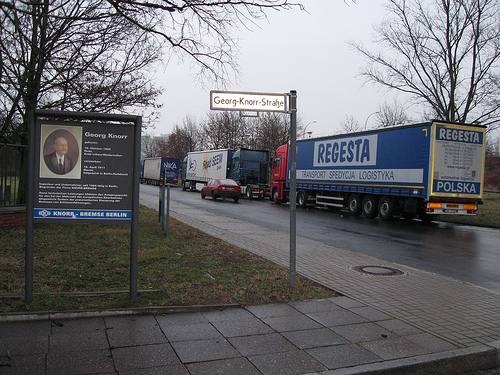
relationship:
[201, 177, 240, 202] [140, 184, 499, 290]
car on street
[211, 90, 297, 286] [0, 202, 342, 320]
sign on grass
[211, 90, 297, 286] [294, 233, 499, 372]
sign on corner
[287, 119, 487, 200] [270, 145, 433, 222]
trailer on semi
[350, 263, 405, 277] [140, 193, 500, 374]
man hole on sidewalk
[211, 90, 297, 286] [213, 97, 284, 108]
sign has lettering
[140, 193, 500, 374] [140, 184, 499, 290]
sidewalk next to street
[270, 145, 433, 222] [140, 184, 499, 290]
semi on street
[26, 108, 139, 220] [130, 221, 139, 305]
sign on pole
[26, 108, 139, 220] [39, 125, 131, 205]
sign has words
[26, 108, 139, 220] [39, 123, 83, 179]
sign has picture